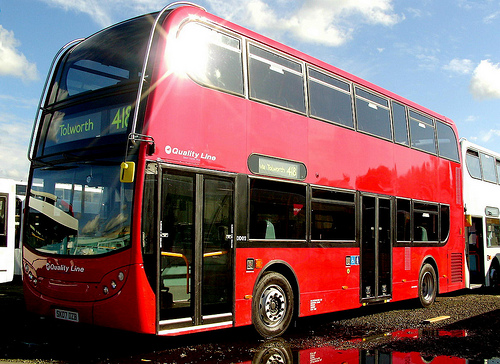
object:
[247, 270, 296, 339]
tire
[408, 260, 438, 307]
tire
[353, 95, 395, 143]
window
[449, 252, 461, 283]
vent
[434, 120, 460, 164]
window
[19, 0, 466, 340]
bus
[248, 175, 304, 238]
window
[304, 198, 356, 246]
window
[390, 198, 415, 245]
window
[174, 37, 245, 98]
window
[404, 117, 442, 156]
window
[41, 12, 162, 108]
window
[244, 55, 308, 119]
window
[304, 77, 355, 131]
window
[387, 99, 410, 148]
window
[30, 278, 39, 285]
headlight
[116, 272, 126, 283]
headlight